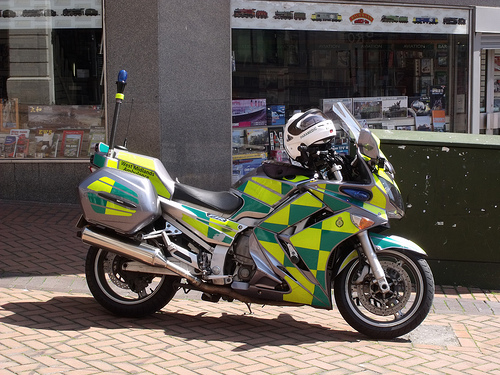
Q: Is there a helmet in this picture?
A: Yes, there is a helmet.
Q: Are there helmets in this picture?
A: Yes, there is a helmet.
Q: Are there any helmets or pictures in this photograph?
A: Yes, there is a helmet.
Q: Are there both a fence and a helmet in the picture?
A: No, there is a helmet but no fences.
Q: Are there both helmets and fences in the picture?
A: No, there is a helmet but no fences.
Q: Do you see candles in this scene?
A: No, there are no candles.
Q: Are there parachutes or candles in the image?
A: No, there are no candles or parachutes.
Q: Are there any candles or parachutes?
A: No, there are no candles or parachutes.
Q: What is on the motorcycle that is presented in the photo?
A: The helmet is on the motorcycle.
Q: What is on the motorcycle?
A: The helmet is on the motorcycle.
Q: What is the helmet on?
A: The helmet is on the motorbike.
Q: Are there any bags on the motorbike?
A: No, there is a helmet on the motorbike.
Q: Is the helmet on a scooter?
A: No, the helmet is on the motorcycle.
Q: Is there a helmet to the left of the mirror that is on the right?
A: Yes, there is a helmet to the left of the mirror.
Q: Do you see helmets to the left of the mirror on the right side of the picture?
A: Yes, there is a helmet to the left of the mirror.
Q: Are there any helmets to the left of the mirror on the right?
A: Yes, there is a helmet to the left of the mirror.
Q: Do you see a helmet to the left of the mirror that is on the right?
A: Yes, there is a helmet to the left of the mirror.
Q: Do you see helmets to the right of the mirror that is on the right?
A: No, the helmet is to the left of the mirror.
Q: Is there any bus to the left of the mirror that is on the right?
A: No, there is a helmet to the left of the mirror.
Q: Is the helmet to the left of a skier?
A: No, the helmet is to the left of a mirror.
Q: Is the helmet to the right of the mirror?
A: No, the helmet is to the left of the mirror.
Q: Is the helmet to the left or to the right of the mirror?
A: The helmet is to the left of the mirror.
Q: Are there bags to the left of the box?
A: No, there is a helmet to the left of the box.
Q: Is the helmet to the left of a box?
A: Yes, the helmet is to the left of a box.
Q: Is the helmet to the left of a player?
A: No, the helmet is to the left of a box.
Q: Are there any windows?
A: Yes, there is a window.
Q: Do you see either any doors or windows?
A: Yes, there is a window.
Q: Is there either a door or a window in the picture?
A: Yes, there is a window.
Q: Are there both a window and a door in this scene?
A: Yes, there are both a window and a door.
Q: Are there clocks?
A: No, there are no clocks.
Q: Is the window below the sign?
A: Yes, the window is below the sign.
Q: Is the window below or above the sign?
A: The window is below the sign.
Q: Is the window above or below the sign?
A: The window is below the sign.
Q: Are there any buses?
A: No, there are no buses.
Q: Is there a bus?
A: No, there are no buses.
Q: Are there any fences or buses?
A: No, there are no buses or fences.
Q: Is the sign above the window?
A: Yes, the sign is above the window.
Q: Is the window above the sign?
A: No, the sign is above the window.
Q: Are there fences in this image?
A: No, there are no fences.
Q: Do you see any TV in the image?
A: No, there are no televisions.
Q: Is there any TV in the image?
A: No, there are no televisions.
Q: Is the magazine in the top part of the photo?
A: Yes, the magazine is in the top of the image.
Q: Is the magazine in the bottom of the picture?
A: No, the magazine is in the top of the image.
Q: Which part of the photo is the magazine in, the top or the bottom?
A: The magazine is in the top of the image.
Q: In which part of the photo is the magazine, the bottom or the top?
A: The magazine is in the top of the image.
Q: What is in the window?
A: The magazine is in the window.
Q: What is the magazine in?
A: The magazine is in the window.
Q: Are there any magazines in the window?
A: Yes, there is a magazine in the window.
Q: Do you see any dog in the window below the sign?
A: No, there is a magazine in the window.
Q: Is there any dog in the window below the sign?
A: No, there is a magazine in the window.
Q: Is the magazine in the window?
A: Yes, the magazine is in the window.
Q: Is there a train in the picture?
A: Yes, there is a train.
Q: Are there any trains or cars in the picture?
A: Yes, there is a train.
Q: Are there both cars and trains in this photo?
A: No, there is a train but no cars.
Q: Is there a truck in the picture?
A: No, there are no trucks.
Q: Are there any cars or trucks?
A: No, there are no trucks or cars.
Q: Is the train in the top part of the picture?
A: Yes, the train is in the top of the image.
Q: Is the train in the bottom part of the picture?
A: No, the train is in the top of the image.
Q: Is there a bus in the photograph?
A: No, there are no buses.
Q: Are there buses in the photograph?
A: No, there are no buses.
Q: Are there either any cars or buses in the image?
A: No, there are no buses or cars.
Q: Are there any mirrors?
A: Yes, there is a mirror.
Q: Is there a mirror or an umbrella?
A: Yes, there is a mirror.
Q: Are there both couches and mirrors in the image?
A: No, there is a mirror but no couches.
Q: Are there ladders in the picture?
A: No, there are no ladders.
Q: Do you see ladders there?
A: No, there are no ladders.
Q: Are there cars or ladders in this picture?
A: No, there are no ladders or cars.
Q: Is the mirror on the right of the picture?
A: Yes, the mirror is on the right of the image.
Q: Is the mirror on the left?
A: No, the mirror is on the right of the image.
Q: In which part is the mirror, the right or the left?
A: The mirror is on the right of the image.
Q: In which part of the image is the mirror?
A: The mirror is on the right of the image.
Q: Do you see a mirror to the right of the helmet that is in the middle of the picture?
A: Yes, there is a mirror to the right of the helmet.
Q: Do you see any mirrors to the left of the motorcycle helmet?
A: No, the mirror is to the right of the helmet.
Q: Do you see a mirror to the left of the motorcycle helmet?
A: No, the mirror is to the right of the helmet.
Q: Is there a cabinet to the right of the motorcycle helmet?
A: No, there is a mirror to the right of the helmet.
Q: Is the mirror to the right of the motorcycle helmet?
A: Yes, the mirror is to the right of the helmet.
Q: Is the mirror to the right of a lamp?
A: No, the mirror is to the right of the helmet.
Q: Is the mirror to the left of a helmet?
A: No, the mirror is to the right of a helmet.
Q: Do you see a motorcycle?
A: Yes, there is a motorcycle.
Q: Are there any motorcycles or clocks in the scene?
A: Yes, there is a motorcycle.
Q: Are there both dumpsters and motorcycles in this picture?
A: No, there is a motorcycle but no dumpsters.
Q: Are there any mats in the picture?
A: No, there are no mats.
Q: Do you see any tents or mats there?
A: No, there are no mats or tents.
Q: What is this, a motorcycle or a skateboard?
A: This is a motorcycle.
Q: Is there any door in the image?
A: Yes, there is a door.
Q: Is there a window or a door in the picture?
A: Yes, there is a door.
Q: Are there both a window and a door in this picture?
A: Yes, there are both a door and a window.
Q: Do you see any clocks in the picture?
A: No, there are no clocks.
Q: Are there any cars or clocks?
A: No, there are no clocks or cars.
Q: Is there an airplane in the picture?
A: No, there are no airplanes.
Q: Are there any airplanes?
A: No, there are no airplanes.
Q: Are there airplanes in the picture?
A: No, there are no airplanes.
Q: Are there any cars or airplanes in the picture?
A: No, there are no airplanes or cars.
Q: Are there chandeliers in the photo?
A: No, there are no chandeliers.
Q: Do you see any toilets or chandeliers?
A: No, there are no chandeliers or toilets.